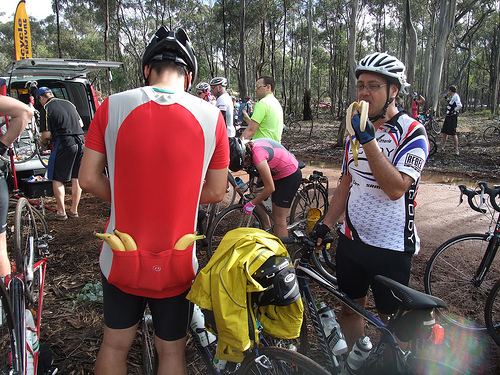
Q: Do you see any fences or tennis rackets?
A: No, there are no fences or tennis rackets.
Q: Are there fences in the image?
A: No, there are no fences.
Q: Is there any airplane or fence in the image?
A: No, there are no fences or airplanes.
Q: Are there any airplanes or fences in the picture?
A: No, there are no fences or airplanes.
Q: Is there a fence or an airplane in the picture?
A: No, there are no fences or airplanes.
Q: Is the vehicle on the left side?
A: Yes, the vehicle is on the left of the image.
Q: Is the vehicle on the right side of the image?
A: No, the vehicle is on the left of the image.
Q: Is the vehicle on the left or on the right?
A: The vehicle is on the left of the image.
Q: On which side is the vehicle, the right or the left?
A: The vehicle is on the left of the image.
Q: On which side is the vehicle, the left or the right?
A: The vehicle is on the left of the image.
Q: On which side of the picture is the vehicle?
A: The vehicle is on the left of the image.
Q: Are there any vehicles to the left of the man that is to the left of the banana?
A: Yes, there is a vehicle to the left of the man.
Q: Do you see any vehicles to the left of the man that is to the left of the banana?
A: Yes, there is a vehicle to the left of the man.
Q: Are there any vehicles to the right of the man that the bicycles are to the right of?
A: No, the vehicle is to the left of the man.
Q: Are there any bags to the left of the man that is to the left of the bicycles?
A: No, there is a vehicle to the left of the man.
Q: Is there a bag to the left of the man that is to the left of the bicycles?
A: No, there is a vehicle to the left of the man.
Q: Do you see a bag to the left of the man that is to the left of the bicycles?
A: No, there is a vehicle to the left of the man.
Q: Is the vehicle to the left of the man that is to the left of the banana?
A: Yes, the vehicle is to the left of the man.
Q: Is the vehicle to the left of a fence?
A: No, the vehicle is to the left of the man.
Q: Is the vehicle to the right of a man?
A: No, the vehicle is to the left of a man.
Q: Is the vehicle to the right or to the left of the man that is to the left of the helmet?
A: The vehicle is to the left of the man.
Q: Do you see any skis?
A: No, there are no skis.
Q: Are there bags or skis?
A: No, there are no skis or bags.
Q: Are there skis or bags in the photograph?
A: No, there are no skis or bags.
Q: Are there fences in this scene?
A: No, there are no fences.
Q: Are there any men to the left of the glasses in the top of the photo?
A: Yes, there is a man to the left of the glasses.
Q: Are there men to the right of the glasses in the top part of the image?
A: No, the man is to the left of the glasses.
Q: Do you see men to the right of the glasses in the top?
A: No, the man is to the left of the glasses.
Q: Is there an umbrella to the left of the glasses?
A: No, there is a man to the left of the glasses.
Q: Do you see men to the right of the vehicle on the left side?
A: Yes, there is a man to the right of the vehicle.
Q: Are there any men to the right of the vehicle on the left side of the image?
A: Yes, there is a man to the right of the vehicle.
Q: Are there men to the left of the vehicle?
A: No, the man is to the right of the vehicle.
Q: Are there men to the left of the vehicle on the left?
A: No, the man is to the right of the vehicle.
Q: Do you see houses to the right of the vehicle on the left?
A: No, there is a man to the right of the vehicle.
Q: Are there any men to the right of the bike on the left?
A: Yes, there is a man to the right of the bike.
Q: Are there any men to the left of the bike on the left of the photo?
A: No, the man is to the right of the bike.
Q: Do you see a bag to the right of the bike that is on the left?
A: No, there is a man to the right of the bike.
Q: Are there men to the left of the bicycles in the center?
A: Yes, there is a man to the left of the bicycles.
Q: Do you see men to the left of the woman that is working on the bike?
A: Yes, there is a man to the left of the woman.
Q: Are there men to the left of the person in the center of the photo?
A: Yes, there is a man to the left of the woman.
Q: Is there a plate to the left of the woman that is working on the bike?
A: No, there is a man to the left of the woman.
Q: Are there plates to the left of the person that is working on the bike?
A: No, there is a man to the left of the woman.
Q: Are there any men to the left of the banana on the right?
A: Yes, there is a man to the left of the banana.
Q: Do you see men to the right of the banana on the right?
A: No, the man is to the left of the banana.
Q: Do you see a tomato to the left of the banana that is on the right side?
A: No, there is a man to the left of the banana.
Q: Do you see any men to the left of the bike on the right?
A: Yes, there is a man to the left of the bike.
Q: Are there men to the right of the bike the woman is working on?
A: No, the man is to the left of the bike.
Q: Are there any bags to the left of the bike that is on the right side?
A: No, there is a man to the left of the bike.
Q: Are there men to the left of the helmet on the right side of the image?
A: Yes, there is a man to the left of the helmet.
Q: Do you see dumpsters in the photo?
A: No, there are no dumpsters.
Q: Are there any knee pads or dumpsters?
A: No, there are no dumpsters or knee pads.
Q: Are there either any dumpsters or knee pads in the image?
A: No, there are no dumpsters or knee pads.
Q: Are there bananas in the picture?
A: Yes, there are bananas.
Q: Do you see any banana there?
A: Yes, there are bananas.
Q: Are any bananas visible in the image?
A: Yes, there are bananas.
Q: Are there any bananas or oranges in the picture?
A: Yes, there are bananas.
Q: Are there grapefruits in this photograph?
A: No, there are no grapefruits.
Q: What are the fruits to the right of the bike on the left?
A: The fruits are bananas.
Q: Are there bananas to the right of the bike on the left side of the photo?
A: Yes, there are bananas to the right of the bike.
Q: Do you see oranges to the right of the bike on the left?
A: No, there are bananas to the right of the bike.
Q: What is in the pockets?
A: The bananas are in the pockets.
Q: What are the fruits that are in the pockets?
A: The fruits are bananas.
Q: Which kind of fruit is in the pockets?
A: The fruits are bananas.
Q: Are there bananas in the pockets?
A: Yes, there are bananas in the pockets.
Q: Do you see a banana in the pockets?
A: Yes, there are bananas in the pockets.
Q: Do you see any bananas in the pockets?
A: Yes, there are bananas in the pockets.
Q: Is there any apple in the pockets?
A: No, there are bananas in the pockets.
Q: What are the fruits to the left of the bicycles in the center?
A: The fruits are bananas.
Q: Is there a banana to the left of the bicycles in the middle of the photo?
A: Yes, there are bananas to the left of the bicycles.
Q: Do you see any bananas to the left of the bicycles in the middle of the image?
A: Yes, there are bananas to the left of the bicycles.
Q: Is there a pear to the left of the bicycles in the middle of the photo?
A: No, there are bananas to the left of the bikes.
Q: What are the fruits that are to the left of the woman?
A: The fruits are bananas.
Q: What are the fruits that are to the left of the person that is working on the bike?
A: The fruits are bananas.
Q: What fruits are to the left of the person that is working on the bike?
A: The fruits are bananas.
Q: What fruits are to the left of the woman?
A: The fruits are bananas.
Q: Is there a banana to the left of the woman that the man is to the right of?
A: Yes, there are bananas to the left of the woman.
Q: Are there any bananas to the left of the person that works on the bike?
A: Yes, there are bananas to the left of the woman.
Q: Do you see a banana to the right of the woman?
A: No, the bananas are to the left of the woman.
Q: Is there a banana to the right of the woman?
A: No, the bananas are to the left of the woman.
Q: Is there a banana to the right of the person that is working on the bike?
A: No, the bananas are to the left of the woman.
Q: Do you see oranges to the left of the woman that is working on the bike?
A: No, there are bananas to the left of the woman.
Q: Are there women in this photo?
A: Yes, there is a woman.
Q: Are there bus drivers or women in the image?
A: Yes, there is a woman.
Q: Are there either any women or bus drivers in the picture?
A: Yes, there is a woman.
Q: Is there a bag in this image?
A: No, there are no bags.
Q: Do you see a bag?
A: No, there are no bags.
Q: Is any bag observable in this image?
A: No, there are no bags.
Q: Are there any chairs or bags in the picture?
A: No, there are no bags or chairs.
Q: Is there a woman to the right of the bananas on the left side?
A: Yes, there is a woman to the right of the bananas.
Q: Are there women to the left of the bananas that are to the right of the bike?
A: No, the woman is to the right of the bananas.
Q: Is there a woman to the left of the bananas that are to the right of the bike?
A: No, the woman is to the right of the bananas.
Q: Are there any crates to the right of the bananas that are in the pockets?
A: No, there is a woman to the right of the bananas.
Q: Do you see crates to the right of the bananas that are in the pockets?
A: No, there is a woman to the right of the bananas.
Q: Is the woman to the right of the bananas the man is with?
A: Yes, the woman is to the right of the bananas.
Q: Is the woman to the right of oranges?
A: No, the woman is to the right of the bananas.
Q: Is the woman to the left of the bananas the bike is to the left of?
A: No, the woman is to the right of the bananas.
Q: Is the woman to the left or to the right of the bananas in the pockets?
A: The woman is to the right of the bananas.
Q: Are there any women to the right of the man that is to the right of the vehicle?
A: Yes, there is a woman to the right of the man.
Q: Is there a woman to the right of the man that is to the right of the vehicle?
A: Yes, there is a woman to the right of the man.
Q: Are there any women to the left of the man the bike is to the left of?
A: No, the woman is to the right of the man.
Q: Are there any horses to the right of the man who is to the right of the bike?
A: No, there is a woman to the right of the man.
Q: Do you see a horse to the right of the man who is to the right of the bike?
A: No, there is a woman to the right of the man.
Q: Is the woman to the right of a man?
A: Yes, the woman is to the right of a man.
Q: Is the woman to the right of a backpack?
A: No, the woman is to the right of a man.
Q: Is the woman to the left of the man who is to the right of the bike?
A: No, the woman is to the right of the man.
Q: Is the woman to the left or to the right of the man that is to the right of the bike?
A: The woman is to the right of the man.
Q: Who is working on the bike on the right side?
A: The woman is working on the bike.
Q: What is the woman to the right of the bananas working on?
A: The woman is working on the bike.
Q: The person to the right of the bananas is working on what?
A: The woman is working on the bike.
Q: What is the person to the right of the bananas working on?
A: The woman is working on the bike.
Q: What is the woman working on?
A: The woman is working on the bike.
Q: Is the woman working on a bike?
A: Yes, the woman is working on a bike.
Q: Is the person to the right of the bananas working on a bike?
A: Yes, the woman is working on a bike.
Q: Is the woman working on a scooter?
A: No, the woman is working on a bike.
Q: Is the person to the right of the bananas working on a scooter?
A: No, the woman is working on a bike.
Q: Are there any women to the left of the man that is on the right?
A: Yes, there is a woman to the left of the man.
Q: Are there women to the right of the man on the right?
A: No, the woman is to the left of the man.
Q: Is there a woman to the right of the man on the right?
A: No, the woman is to the left of the man.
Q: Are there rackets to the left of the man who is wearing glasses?
A: No, there is a woman to the left of the man.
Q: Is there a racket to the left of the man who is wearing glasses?
A: No, there is a woman to the left of the man.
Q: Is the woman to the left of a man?
A: Yes, the woman is to the left of a man.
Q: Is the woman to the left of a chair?
A: No, the woman is to the left of a man.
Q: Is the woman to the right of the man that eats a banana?
A: No, the woman is to the left of the man.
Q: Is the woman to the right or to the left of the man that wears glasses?
A: The woman is to the left of the man.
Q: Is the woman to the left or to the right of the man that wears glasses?
A: The woman is to the left of the man.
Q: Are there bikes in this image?
A: Yes, there are bikes.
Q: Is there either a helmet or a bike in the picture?
A: Yes, there are bikes.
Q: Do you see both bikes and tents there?
A: No, there are bikes but no tents.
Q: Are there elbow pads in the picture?
A: No, there are no elbow pads.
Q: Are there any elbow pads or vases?
A: No, there are no elbow pads or vases.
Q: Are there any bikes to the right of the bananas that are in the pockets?
A: Yes, there are bikes to the right of the bananas.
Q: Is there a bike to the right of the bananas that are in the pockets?
A: Yes, there are bikes to the right of the bananas.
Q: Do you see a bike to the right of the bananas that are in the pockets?
A: Yes, there are bikes to the right of the bananas.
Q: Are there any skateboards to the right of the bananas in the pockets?
A: No, there are bikes to the right of the bananas.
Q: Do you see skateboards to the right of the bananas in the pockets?
A: No, there are bikes to the right of the bananas.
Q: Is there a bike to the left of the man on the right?
A: Yes, there are bikes to the left of the man.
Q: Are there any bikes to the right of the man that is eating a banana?
A: No, the bikes are to the left of the man.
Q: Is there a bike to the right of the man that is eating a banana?
A: No, the bikes are to the left of the man.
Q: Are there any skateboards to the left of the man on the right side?
A: No, there are bikes to the left of the man.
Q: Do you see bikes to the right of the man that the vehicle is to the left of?
A: Yes, there are bikes to the right of the man.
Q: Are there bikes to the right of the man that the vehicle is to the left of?
A: Yes, there are bikes to the right of the man.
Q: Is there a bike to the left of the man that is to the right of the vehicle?
A: No, the bikes are to the right of the man.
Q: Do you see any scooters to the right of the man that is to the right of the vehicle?
A: No, there are bikes to the right of the man.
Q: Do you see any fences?
A: No, there are no fences.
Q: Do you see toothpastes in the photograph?
A: No, there are no toothpastes.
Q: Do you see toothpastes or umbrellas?
A: No, there are no toothpastes or umbrellas.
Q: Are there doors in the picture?
A: Yes, there is a door.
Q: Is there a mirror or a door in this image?
A: Yes, there is a door.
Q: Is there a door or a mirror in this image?
A: Yes, there is a door.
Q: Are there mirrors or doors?
A: Yes, there is a door.